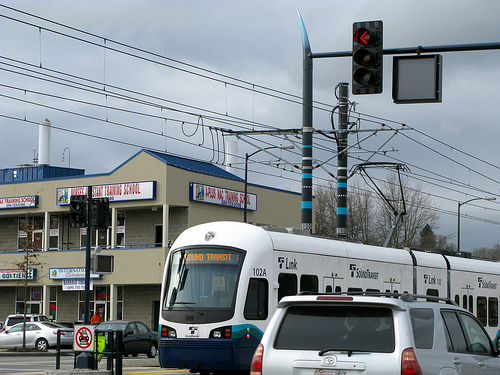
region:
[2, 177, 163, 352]
the facade of a building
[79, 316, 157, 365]
a car parked in front of a building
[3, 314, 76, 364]
a car parked in front of a building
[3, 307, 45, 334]
a car parked in front of a building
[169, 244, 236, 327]
the front of a passenger train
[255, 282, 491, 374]
a car parked on the side of the road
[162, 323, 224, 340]
the headlights of a train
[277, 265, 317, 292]
the door of a train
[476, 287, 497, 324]
the windows of a train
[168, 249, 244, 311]
the windshield of a train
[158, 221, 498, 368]
commuter light rail train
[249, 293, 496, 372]
silver station wagon style car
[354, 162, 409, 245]
light rail electrical connection from train to overhead wires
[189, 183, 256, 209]
white plastic business sign with white letters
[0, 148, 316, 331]
two story commercial business building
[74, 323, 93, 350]
square red white and black traffic sign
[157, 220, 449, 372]
Puget Sound Washington SoundTransit light rail train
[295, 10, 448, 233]
metal pole with two electronic traffic signs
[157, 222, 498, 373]
dark blue, white and light blue Sound Transit Link light rail train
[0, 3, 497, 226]
overhead wires for electric SoundTransit Link trains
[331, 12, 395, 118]
a red arrow sign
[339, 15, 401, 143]
a black traffic light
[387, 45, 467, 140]
a black traffic screen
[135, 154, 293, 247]
a white and red sign on a building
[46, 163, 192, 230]
a white and red sign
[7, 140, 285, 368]
a tan building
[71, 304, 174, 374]
a black car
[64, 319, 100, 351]
a red and white traffic sign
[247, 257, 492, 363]
a silver suv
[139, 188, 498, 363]
a white bus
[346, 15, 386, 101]
three light traffic signal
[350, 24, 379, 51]
red left turn signal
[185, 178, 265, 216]
red and white rectangular store sign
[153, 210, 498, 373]
white city passenger train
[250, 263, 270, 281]
train identification number above side window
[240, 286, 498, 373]
side back view of silver suv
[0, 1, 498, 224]
electrical lines for powering train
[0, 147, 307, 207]
blue roof on distant building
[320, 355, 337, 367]
toyota logo on back of suv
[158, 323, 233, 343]
headlights on passenger train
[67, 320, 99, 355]
white square sign with red circle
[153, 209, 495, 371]
long white train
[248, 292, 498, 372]
silver SUV car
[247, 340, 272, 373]
red tail light of a car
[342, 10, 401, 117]
black metal traffic light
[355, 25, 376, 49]
red arrow in traffic light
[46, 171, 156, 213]
white sign with red text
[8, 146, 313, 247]
tan building with blue roof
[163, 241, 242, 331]
windshield of a train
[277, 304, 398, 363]
window on a car